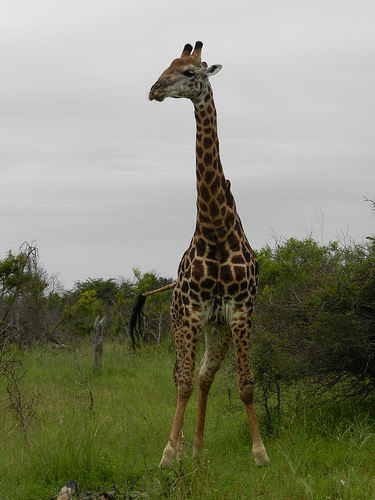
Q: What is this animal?
A: Giraffe.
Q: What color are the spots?
A: Brown.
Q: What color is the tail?
A: Black.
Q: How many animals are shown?
A: One.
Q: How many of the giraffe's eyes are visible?
A: One.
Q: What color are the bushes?
A: Green.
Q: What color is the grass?
A: Green.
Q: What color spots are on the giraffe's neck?
A: Brown.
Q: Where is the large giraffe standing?
A: In the brush.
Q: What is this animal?
A: A tall spotted giraffe.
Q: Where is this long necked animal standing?
A: Amid vegetation.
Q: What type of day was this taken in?
A: Overcast sky.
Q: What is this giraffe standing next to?
A: Some bushes.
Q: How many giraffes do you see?
A: One.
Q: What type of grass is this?
A: Wild.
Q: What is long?
A: Giraffe's neck.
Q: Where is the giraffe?
A: In the field.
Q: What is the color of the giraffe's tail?
A: Black and brown.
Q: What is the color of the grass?
A: Green.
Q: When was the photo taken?
A: Daytime.